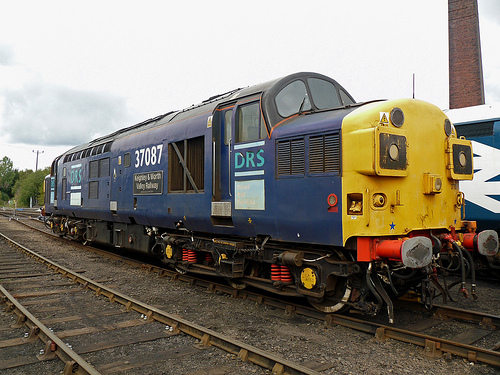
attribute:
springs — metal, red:
[264, 261, 290, 284]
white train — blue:
[442, 101, 499, 283]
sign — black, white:
[129, 172, 167, 199]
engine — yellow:
[56, 70, 498, 323]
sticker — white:
[377, 110, 389, 124]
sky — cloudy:
[4, 2, 497, 147]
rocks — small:
[241, 317, 461, 373]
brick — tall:
[447, 81, 459, 91]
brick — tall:
[465, 73, 476, 80]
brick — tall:
[451, 50, 462, 56]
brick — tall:
[459, 8, 476, 13]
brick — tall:
[466, 93, 478, 103]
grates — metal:
[272, 128, 346, 181]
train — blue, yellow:
[71, 38, 497, 336]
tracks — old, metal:
[0, 212, 499, 367]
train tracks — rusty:
[2, 207, 497, 373]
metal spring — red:
[265, 259, 292, 286]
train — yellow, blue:
[28, 57, 497, 322]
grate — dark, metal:
[306, 131, 342, 177]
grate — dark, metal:
[272, 134, 306, 178]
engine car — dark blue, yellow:
[40, 73, 479, 324]